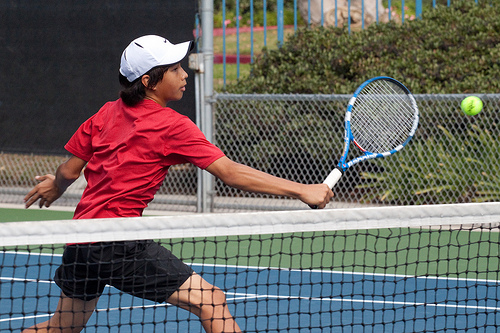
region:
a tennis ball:
[458, 93, 485, 118]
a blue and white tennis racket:
[311, 76, 422, 199]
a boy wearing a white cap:
[122, 37, 190, 108]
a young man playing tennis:
[21, 23, 486, 328]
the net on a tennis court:
[3, 206, 498, 331]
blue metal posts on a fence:
[218, 0, 254, 85]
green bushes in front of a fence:
[219, 0, 495, 91]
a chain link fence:
[218, 93, 499, 210]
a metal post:
[197, 4, 214, 209]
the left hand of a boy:
[21, 171, 60, 208]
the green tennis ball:
[457, 95, 482, 115]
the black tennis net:
[1, 242, 497, 332]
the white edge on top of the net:
[0, 197, 498, 240]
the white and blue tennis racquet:
[322, 75, 419, 204]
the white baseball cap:
[118, 35, 190, 80]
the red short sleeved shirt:
[63, 97, 223, 220]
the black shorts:
[53, 236, 191, 302]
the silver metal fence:
[211, 85, 498, 195]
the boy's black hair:
[116, 63, 164, 103]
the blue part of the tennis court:
[249, 299, 395, 331]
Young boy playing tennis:
[11, 17, 292, 332]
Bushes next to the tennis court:
[215, 6, 499, 193]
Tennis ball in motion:
[445, 80, 496, 132]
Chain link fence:
[211, 77, 498, 227]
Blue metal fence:
[214, 0, 486, 83]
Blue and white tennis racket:
[270, 60, 427, 206]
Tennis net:
[1, 192, 497, 328]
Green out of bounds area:
[1, 190, 496, 287]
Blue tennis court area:
[0, 230, 497, 332]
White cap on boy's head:
[93, 17, 217, 102]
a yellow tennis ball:
[446, 73, 499, 147]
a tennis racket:
[258, 29, 454, 227]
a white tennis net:
[5, 180, 477, 329]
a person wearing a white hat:
[91, 22, 232, 149]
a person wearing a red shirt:
[16, 3, 233, 238]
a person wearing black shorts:
[26, 28, 268, 310]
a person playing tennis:
[28, 3, 473, 247]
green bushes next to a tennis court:
[226, 18, 498, 328]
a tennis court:
[23, 46, 475, 319]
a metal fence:
[196, 65, 497, 182]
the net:
[240, 228, 362, 325]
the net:
[338, 268, 372, 320]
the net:
[295, 281, 336, 323]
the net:
[315, 238, 359, 293]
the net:
[315, 275, 356, 323]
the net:
[291, 260, 352, 301]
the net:
[334, 252, 394, 320]